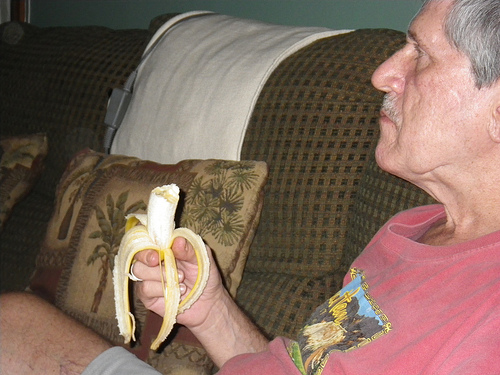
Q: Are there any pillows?
A: Yes, there is a pillow.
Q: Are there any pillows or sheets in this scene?
A: Yes, there is a pillow.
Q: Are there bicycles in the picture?
A: No, there are no bicycles.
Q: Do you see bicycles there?
A: No, there are no bicycles.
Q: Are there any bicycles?
A: No, there are no bicycles.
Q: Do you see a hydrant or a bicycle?
A: No, there are no bicycles or fire hydrants.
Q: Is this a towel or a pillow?
A: This is a pillow.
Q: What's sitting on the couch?
A: The pillow is sitting on the couch.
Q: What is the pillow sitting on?
A: The pillow is sitting on the couch.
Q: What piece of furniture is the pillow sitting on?
A: The pillow is sitting on the couch.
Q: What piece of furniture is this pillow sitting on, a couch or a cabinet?
A: The pillow is sitting on a couch.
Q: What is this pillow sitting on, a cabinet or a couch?
A: The pillow is sitting on a couch.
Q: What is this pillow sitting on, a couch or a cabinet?
A: The pillow is sitting on a couch.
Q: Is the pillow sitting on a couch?
A: Yes, the pillow is sitting on a couch.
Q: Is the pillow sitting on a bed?
A: No, the pillow is sitting on a couch.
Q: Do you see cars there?
A: No, there are no cars.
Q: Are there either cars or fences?
A: No, there are no cars or fences.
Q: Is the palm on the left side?
A: Yes, the palm is on the left of the image.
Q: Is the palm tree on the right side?
A: No, the palm tree is on the left of the image.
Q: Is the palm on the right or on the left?
A: The palm is on the left of the image.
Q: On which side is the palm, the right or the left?
A: The palm is on the left of the image.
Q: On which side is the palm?
A: The palm is on the left of the image.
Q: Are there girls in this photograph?
A: No, there are no girls.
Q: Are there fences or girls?
A: No, there are no girls or fences.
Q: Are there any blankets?
A: Yes, there is a blanket.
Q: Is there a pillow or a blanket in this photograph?
A: Yes, there is a blanket.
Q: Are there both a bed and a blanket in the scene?
A: No, there is a blanket but no beds.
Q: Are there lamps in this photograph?
A: No, there are no lamps.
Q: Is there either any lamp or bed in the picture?
A: No, there are no lamps or beds.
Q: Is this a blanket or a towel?
A: This is a blanket.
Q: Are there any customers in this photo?
A: No, there are no customers.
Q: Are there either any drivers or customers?
A: No, there are no customers or drivers.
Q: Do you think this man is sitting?
A: Yes, the man is sitting.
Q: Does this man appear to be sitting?
A: Yes, the man is sitting.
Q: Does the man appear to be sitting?
A: Yes, the man is sitting.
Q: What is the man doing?
A: The man is sitting.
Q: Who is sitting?
A: The man is sitting.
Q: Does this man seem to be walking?
A: No, the man is sitting.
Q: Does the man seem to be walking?
A: No, the man is sitting.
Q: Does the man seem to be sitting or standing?
A: The man is sitting.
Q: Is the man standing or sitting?
A: The man is sitting.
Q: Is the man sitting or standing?
A: The man is sitting.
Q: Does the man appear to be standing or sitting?
A: The man is sitting.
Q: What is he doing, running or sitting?
A: The man is sitting.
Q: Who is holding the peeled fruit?
A: The man is holding the banana.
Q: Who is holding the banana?
A: The man is holding the banana.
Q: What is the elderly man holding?
A: The man is holding the banana.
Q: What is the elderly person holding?
A: The man is holding the banana.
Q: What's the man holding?
A: The man is holding the banana.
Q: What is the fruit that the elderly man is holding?
A: The fruit is a banana.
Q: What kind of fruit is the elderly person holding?
A: The man is holding the banana.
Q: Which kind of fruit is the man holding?
A: The man is holding the banana.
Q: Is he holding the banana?
A: Yes, the man is holding the banana.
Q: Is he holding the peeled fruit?
A: Yes, the man is holding the banana.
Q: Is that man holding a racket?
A: No, the man is holding the banana.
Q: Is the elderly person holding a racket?
A: No, the man is holding the banana.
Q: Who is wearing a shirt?
A: The man is wearing a shirt.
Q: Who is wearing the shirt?
A: The man is wearing a shirt.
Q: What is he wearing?
A: The man is wearing a shirt.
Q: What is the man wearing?
A: The man is wearing a shirt.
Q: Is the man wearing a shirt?
A: Yes, the man is wearing a shirt.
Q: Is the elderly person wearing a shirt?
A: Yes, the man is wearing a shirt.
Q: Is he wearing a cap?
A: No, the man is wearing a shirt.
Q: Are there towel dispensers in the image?
A: No, there are no towel dispensers.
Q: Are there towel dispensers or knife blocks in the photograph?
A: No, there are no towel dispensers or knife blocks.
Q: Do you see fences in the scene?
A: No, there are no fences.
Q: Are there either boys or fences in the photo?
A: No, there are no fences or boys.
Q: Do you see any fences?
A: No, there are no fences.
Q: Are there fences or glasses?
A: No, there are no fences or glasses.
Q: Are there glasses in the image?
A: No, there are no glasses.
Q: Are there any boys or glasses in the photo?
A: No, there are no glasses or boys.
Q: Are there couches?
A: Yes, there is a couch.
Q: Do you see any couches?
A: Yes, there is a couch.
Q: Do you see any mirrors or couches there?
A: Yes, there is a couch.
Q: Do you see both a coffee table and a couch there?
A: No, there is a couch but no coffee tables.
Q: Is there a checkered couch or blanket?
A: Yes, there is a checkered couch.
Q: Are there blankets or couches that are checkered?
A: Yes, the couch is checkered.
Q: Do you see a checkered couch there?
A: Yes, there is a checkered couch.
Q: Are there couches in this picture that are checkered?
A: Yes, there is a couch that is checkered.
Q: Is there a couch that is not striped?
A: Yes, there is a checkered couch.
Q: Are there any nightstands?
A: No, there are no nightstands.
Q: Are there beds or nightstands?
A: No, there are no nightstands or beds.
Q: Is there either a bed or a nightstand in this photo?
A: No, there are no nightstands or beds.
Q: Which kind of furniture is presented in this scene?
A: The furniture is a couch.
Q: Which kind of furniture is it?
A: The piece of furniture is a couch.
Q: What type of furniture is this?
A: That is a couch.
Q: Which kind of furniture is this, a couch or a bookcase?
A: That is a couch.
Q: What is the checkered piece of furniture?
A: The piece of furniture is a couch.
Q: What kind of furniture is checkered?
A: The furniture is a couch.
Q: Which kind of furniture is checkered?
A: The furniture is a couch.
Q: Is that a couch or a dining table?
A: That is a couch.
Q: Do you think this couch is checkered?
A: Yes, the couch is checkered.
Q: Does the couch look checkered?
A: Yes, the couch is checkered.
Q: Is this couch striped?
A: No, the couch is checkered.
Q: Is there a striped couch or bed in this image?
A: No, there is a couch but it is checkered.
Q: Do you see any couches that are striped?
A: No, there is a couch but it is checkered.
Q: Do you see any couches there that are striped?
A: No, there is a couch but it is checkered.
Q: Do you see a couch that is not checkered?
A: No, there is a couch but it is checkered.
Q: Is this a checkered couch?
A: Yes, this is a checkered couch.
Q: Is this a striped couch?
A: No, this is a checkered couch.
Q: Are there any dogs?
A: No, there are no dogs.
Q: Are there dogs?
A: No, there are no dogs.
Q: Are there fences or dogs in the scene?
A: No, there are no dogs or fences.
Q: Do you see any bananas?
A: Yes, there is a banana.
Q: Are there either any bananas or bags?
A: Yes, there is a banana.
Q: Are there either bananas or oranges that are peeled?
A: Yes, the banana is peeled.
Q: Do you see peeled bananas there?
A: Yes, there is a peeled banana.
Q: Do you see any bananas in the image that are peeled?
A: Yes, there is a banana that is peeled.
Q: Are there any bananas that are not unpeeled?
A: Yes, there is an peeled banana.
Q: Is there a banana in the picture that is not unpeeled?
A: Yes, there is an peeled banana.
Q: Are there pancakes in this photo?
A: No, there are no pancakes.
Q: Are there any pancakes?
A: No, there are no pancakes.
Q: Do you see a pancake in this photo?
A: No, there are no pancakes.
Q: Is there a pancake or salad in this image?
A: No, there are no pancakes or salad.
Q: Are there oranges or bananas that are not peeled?
A: No, there is a banana but it is peeled.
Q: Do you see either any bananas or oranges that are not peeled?
A: No, there is a banana but it is peeled.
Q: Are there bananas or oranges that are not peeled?
A: No, there is a banana but it is peeled.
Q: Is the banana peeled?
A: Yes, the banana is peeled.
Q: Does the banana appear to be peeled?
A: Yes, the banana is peeled.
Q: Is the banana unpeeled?
A: No, the banana is peeled.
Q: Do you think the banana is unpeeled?
A: No, the banana is peeled.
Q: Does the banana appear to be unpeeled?
A: No, the banana is peeled.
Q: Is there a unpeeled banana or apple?
A: No, there is a banana but it is peeled.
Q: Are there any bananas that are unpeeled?
A: No, there is a banana but it is peeled.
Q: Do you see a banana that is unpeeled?
A: No, there is a banana but it is peeled.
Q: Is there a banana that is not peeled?
A: No, there is a banana but it is peeled.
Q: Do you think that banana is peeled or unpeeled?
A: The banana is peeled.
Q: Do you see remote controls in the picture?
A: Yes, there is a remote control.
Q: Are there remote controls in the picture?
A: Yes, there is a remote control.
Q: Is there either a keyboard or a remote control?
A: Yes, there is a remote control.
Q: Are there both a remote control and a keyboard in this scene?
A: No, there is a remote control but no keyboards.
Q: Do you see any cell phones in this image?
A: No, there are no cell phones.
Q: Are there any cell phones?
A: No, there are no cell phones.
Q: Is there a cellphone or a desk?
A: No, there are no cell phones or desks.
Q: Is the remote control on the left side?
A: Yes, the remote control is on the left of the image.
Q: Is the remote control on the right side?
A: No, the remote control is on the left of the image.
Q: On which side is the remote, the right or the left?
A: The remote is on the left of the image.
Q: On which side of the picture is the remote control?
A: The remote control is on the left of the image.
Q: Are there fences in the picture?
A: No, there are no fences.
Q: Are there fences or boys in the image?
A: No, there are no fences or boys.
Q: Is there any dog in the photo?
A: No, there are no dogs.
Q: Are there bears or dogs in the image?
A: No, there are no dogs or bears.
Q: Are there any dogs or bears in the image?
A: No, there are no dogs or bears.